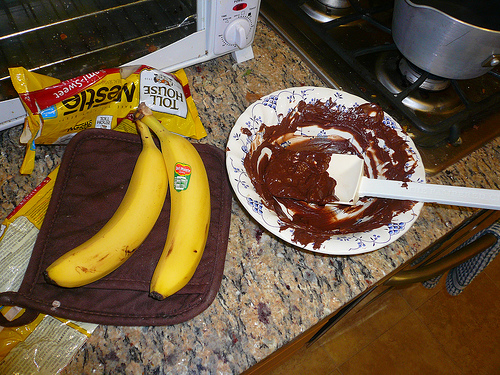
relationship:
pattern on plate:
[246, 188, 266, 219] [223, 72, 436, 256]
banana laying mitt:
[137, 104, 213, 300] [59, 149, 117, 220]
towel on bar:
[425, 227, 499, 295] [386, 240, 493, 286]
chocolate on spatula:
[236, 101, 424, 251] [260, 142, 499, 216]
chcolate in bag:
[6, 63, 209, 146] [11, 67, 203, 146]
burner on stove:
[361, 32, 481, 132] [265, 2, 487, 146]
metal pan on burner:
[395, 0, 499, 78] [367, 53, 469, 116]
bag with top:
[11, 67, 203, 146] [2, 103, 45, 175]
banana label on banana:
[173, 162, 193, 193] [142, 107, 212, 296]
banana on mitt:
[136, 104, 214, 304] [0, 125, 232, 328]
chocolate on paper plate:
[236, 101, 424, 251] [222, 82, 430, 260]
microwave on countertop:
[0, 0, 261, 135] [3, 15, 498, 369]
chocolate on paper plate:
[271, 146, 328, 214] [222, 82, 430, 260]